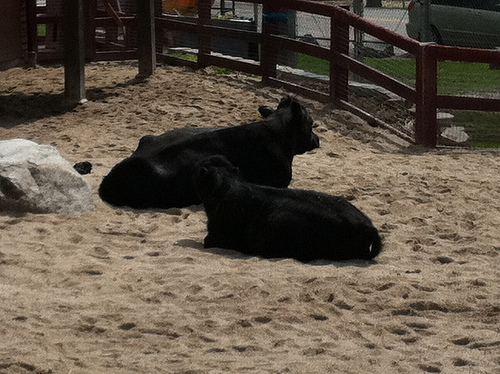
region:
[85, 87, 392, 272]
Baby cow resting in a pen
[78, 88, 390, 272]
Baby cow resting in a pen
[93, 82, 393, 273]
Baby cow resting in a pen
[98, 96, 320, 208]
a big black cow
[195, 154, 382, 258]
a big black calf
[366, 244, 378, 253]
a region of white hair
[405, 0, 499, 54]
a mini van parked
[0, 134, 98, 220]
a big solid rock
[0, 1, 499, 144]
red fence with metal nets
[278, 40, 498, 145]
a region of green grass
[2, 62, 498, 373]
sand with footprints in it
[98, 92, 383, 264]
two cows sitting on the sand